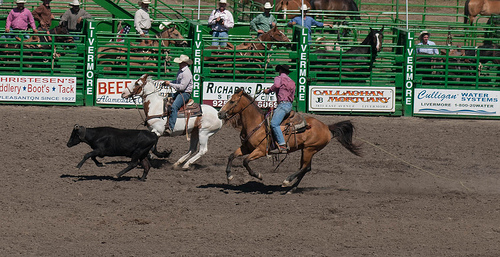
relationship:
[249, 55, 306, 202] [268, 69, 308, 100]
man in shirt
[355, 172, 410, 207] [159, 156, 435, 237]
dirt on ground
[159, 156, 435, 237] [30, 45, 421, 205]
ground of stable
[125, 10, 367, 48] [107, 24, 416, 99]
men behind fence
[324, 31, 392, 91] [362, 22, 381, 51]
horse with stripe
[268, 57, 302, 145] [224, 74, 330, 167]
man riding horse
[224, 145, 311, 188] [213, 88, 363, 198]
legs of horse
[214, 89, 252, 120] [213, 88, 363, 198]
head of horse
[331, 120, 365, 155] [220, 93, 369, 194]
tail of horse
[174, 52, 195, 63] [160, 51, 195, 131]
hat of man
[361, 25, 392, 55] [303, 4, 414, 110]
horse behind gate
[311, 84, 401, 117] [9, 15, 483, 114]
advertisement on wall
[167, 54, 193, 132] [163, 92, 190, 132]
man wearing jeans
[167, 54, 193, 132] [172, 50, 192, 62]
man wearing cowboy hat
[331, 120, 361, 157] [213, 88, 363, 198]
tail on horse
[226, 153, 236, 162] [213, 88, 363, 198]
knee on horse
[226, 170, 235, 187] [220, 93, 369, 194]
hoof of horse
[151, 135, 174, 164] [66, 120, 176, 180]
tail on bull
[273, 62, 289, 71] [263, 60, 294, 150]
hat on man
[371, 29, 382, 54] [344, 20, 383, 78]
face of horse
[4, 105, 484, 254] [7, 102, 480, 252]
dirt in field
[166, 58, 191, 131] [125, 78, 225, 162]
man riding horse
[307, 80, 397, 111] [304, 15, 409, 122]
advertisement on wall